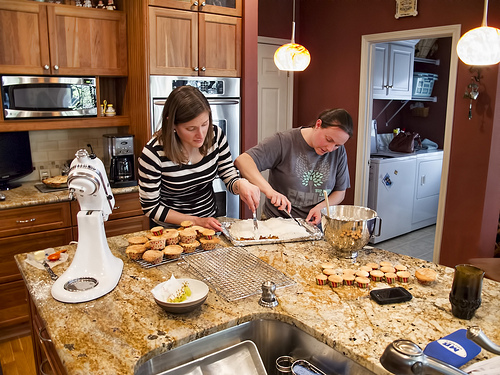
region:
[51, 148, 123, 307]
A white mixer base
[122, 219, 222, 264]
baked iced muffins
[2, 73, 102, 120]
A shiny silver microwave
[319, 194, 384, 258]
A shiny silver mixing bowl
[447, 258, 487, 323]
A dark colored drink cup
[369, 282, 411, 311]
A black smart phone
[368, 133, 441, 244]
A white washer and dryer set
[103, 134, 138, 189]
A silver coffee maker on the counter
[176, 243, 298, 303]
An empty cooling rack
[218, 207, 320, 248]
a pan of baked goods getting iced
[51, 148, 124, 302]
A white electric mixer.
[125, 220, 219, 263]
a wire rack filled with cupcakes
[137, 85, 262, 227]
A woman cutting a cake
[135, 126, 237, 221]
a woman's black and white shirt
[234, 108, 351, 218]
a woman in a grey shirt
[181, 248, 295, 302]
a wire baking rack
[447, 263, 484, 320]
a dark glass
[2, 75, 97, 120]
a chrome microwave oven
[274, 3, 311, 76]
a hanging glass lamp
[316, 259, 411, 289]
cupcakes sitting on a counter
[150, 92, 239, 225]
woman baking in kitchen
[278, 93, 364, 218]
woman baking in kitchen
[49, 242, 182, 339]
granite counter in kitchen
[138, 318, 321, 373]
metal sink cut into counter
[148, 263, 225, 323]
small white bowl on counter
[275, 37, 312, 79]
light hanging from ceiling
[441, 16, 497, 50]
light hanging from ceiling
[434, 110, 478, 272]
red wall on kitchen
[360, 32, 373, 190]
whtie door frame of kitchen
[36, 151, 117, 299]
white blender on counter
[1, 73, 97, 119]
silver microwave on shelf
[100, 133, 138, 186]
coffee maker on counter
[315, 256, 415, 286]
cupcakes on counter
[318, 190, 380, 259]
silver mixing bowl on counter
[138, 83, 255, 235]
woman wearing black and white striped shirt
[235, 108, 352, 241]
woman frosting cake in kitchen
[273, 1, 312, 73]
light hanging from kitchen ceiling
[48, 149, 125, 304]
white standing mixer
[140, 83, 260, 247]
woman working on counter in kitchen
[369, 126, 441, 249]
white washer and dryer in laundry room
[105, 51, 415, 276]
two women cooking together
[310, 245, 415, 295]
several minature cupcakes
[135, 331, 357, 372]
a sink full of dishes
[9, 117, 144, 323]
a white standing mixer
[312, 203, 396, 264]
a silver bowl to mixer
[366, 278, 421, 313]
a black cellphone on counter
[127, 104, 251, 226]
a black and white shirt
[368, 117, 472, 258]
a washer and dryer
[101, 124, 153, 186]
a silver coffee maker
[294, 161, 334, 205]
green leaves on her shirt